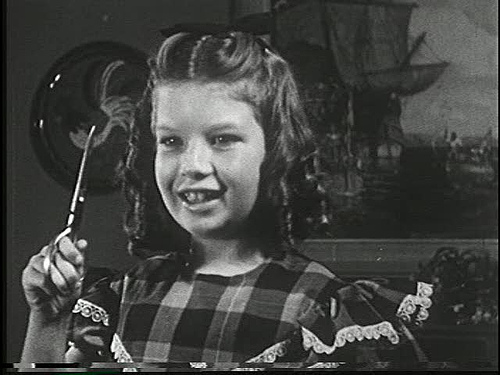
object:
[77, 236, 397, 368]
dress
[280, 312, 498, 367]
mantle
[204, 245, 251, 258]
neck/part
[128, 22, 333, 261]
open sign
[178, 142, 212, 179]
nose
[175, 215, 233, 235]
chin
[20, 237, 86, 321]
hand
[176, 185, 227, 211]
smile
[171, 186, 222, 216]
mouth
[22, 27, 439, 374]
girl